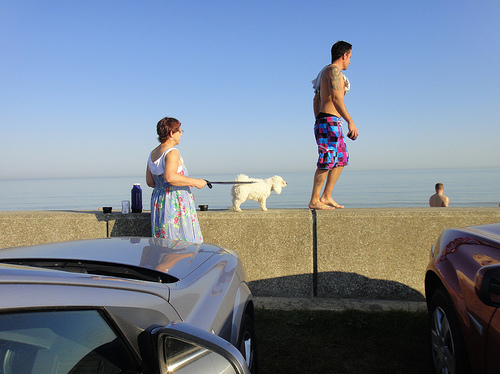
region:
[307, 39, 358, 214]
man wearing colorful shorts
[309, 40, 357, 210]
man carrying white shirt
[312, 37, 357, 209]
man has shoulder tattoo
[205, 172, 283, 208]
white dog on leash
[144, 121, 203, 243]
woman in blue dress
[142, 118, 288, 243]
woman walking white dog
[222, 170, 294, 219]
dog standing on ledge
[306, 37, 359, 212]
man walking on ledge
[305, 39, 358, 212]
man is bare foot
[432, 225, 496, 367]
parked car is red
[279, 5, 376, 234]
man standing on a ledge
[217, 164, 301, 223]
dog standing on the ledge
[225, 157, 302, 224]
the dog is white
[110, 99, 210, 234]
the woman is holding the dogs leash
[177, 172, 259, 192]
the leash is black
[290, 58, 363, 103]
man has a towel over his shoulder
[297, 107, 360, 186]
man is wearing shorts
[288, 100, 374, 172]
the shorts are colorful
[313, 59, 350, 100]
a tattoo on the shoulder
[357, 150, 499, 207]
the water is still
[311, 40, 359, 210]
a standing shirtless man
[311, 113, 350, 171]
blue and pink board shorts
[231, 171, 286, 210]
a small white dog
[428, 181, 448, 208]
a shirtless man in distance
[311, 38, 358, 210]
a man with tattoos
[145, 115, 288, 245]
a woman walking a dog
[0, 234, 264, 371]
a parked grey car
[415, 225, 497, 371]
a parked red car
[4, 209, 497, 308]
a short concrete wall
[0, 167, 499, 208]
a body of water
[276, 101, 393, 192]
man's shorts are blue and purple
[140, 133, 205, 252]
woman's dress is blue and white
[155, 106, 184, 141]
woman is wearing glasses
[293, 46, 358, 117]
man not wearing a shirt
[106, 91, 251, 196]
woman is holding leash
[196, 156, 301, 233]
dog standing on concrete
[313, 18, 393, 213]
man standing on concrete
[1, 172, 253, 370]
the car is gray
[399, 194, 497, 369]
the car is red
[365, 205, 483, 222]
large section of gray wall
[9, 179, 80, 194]
very calm blue ocean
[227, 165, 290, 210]
white poodle on wall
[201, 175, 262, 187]
black leash holding dog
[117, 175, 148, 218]
green bottle on wall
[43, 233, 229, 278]
hood of silver car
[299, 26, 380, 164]
man standing on wall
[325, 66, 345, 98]
tattoo on man's arm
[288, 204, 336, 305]
split line in the sidewalk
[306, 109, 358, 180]
red and blue shorts